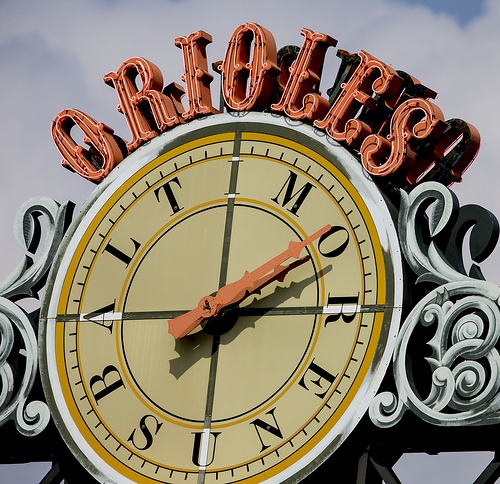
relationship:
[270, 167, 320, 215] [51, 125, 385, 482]
letter on clock face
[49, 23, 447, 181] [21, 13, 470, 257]
orioles on sign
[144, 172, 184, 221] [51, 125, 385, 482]
letter on clock face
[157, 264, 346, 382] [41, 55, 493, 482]
shadow on clock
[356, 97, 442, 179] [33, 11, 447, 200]
letter of sign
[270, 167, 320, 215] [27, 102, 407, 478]
letter on clock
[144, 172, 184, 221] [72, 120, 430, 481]
letter on clock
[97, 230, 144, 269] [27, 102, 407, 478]
letter from clock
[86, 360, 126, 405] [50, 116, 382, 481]
letter on clock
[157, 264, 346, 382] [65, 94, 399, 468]
shadow of clock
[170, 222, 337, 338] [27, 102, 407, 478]
hand on clock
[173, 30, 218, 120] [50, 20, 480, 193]
letter on sign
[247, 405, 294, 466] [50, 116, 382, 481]
letter on clock